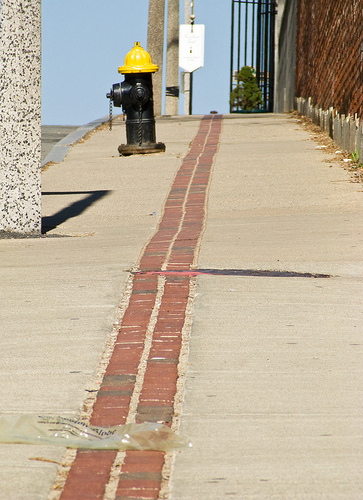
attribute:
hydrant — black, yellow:
[106, 39, 167, 155]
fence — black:
[216, 11, 304, 126]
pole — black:
[186, 67, 195, 109]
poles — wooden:
[176, 0, 197, 113]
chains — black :
[85, 95, 144, 145]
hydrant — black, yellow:
[103, 38, 158, 158]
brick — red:
[114, 487, 160, 498]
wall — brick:
[295, 2, 362, 123]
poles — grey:
[0, 4, 203, 159]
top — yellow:
[114, 37, 162, 73]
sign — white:
[176, 21, 208, 73]